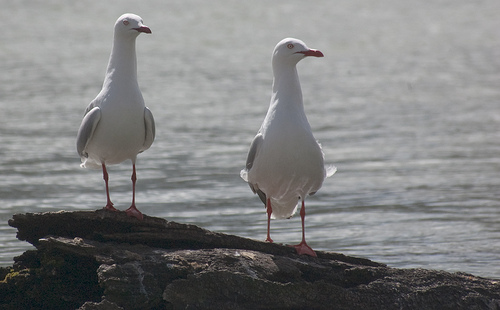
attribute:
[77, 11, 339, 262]
two birds — pictured, looking to left, at the shore, white, alert, grey, looking right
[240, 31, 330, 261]
bird — white, looking to left, grey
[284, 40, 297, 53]
eye — yellow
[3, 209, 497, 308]
rocks — brown, rotten, wooden, black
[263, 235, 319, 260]
feet — webbed, orange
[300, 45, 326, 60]
beak — orange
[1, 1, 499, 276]
water — calm, choppy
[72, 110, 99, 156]
wing — grey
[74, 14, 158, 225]
bird — white, grey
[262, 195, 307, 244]
legs — orange, red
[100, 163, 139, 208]
legs — orange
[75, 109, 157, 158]
wings — gray